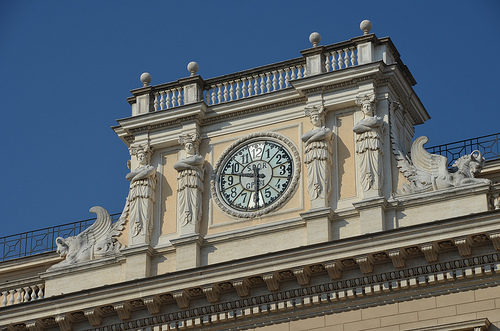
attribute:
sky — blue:
[3, 4, 498, 248]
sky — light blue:
[2, 4, 497, 202]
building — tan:
[27, 77, 484, 329]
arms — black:
[221, 159, 282, 207]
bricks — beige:
[376, 276, 497, 327]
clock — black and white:
[164, 133, 361, 250]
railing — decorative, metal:
[413, 128, 499, 167]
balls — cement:
[130, 11, 385, 92]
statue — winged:
[394, 137, 495, 190]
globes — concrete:
[129, 60, 244, 95]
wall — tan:
[0, 15, 497, 330]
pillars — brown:
[126, 33, 417, 106]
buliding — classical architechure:
[0, 26, 492, 325]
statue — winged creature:
[403, 134, 486, 199]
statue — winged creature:
[50, 194, 112, 259]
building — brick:
[3, 11, 499, 326]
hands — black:
[203, 126, 272, 191]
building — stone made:
[129, 84, 368, 319]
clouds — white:
[104, 24, 179, 63]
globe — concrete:
[359, 16, 374, 33]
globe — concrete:
[309, 27, 322, 44]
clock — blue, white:
[215, 137, 295, 216]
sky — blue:
[11, 22, 122, 203]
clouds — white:
[17, 160, 119, 203]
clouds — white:
[35, 55, 99, 84]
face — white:
[218, 138, 291, 208]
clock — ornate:
[199, 128, 342, 259]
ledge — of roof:
[136, 196, 496, 314]